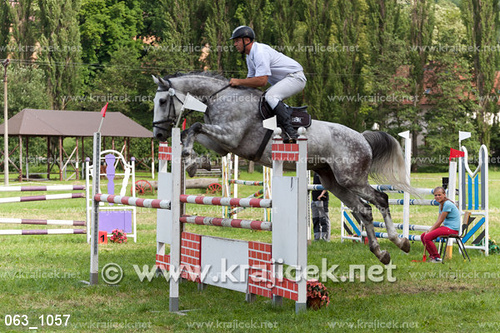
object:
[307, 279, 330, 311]
flowers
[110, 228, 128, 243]
flowers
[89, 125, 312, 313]
barrier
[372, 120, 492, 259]
barrier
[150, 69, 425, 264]
horse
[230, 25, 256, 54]
helmet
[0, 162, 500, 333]
grass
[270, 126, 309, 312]
poles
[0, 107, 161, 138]
shade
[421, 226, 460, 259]
red pants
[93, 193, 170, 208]
bars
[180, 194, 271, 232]
bars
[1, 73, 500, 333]
race field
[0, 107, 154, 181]
awning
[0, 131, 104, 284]
barrier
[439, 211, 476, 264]
chair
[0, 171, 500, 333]
lawn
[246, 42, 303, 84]
white shirt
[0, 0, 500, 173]
tree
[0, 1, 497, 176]
obscured view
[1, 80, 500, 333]
training area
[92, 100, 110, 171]
red flag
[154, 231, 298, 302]
bricks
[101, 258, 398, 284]
watermark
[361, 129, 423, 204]
tail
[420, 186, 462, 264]
girl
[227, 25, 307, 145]
man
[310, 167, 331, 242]
person